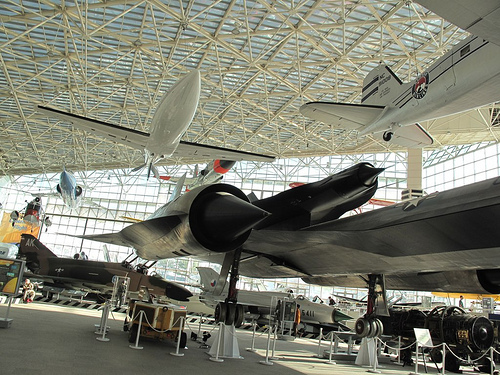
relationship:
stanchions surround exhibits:
[94, 290, 206, 345] [131, 140, 497, 338]